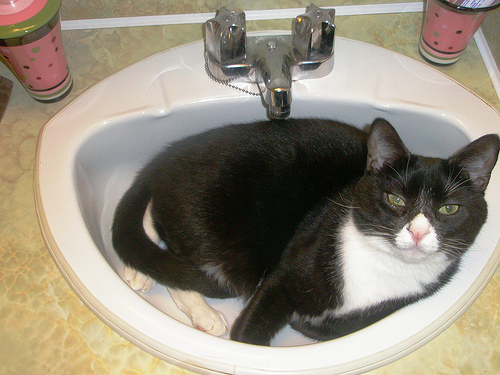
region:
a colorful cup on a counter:
[0, 0, 75, 101]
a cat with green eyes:
[387, 190, 461, 220]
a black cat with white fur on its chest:
[337, 203, 454, 315]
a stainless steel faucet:
[199, 5, 340, 122]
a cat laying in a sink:
[112, 112, 499, 344]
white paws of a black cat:
[118, 203, 225, 337]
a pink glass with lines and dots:
[418, 3, 498, 65]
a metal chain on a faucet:
[203, 57, 260, 97]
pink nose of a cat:
[408, 225, 428, 247]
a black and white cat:
[113, 111, 498, 346]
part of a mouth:
[397, 235, 422, 259]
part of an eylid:
[393, 180, 408, 197]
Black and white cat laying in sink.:
[110, 118, 498, 348]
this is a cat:
[176, 125, 433, 296]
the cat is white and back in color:
[313, 183, 378, 284]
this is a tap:
[254, 38, 304, 105]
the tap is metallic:
[254, 28, 289, 121]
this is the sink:
[98, 82, 150, 142]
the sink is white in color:
[130, 75, 170, 129]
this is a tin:
[7, 5, 72, 87]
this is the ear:
[366, 120, 416, 156]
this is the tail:
[113, 209, 148, 258]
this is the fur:
[441, 167, 468, 192]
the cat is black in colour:
[146, 85, 498, 362]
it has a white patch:
[306, 210, 469, 331]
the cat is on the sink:
[97, 60, 493, 347]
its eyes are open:
[313, 151, 471, 278]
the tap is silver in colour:
[196, 8, 347, 134]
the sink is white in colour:
[57, 82, 496, 351]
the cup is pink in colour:
[1, 2, 100, 94]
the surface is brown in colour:
[15, 290, 120, 374]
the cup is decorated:
[405, 0, 499, 78]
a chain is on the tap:
[192, 45, 289, 119]